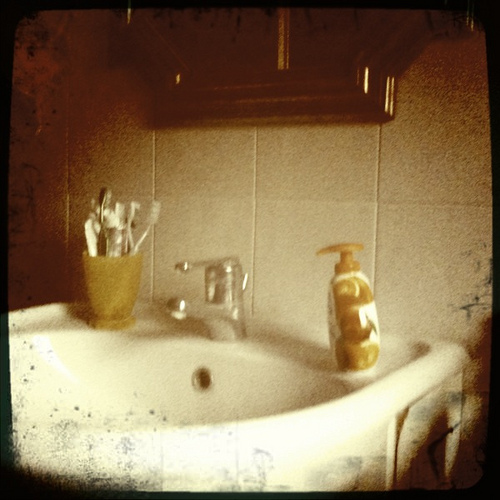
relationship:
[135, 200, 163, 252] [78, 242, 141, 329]
toothbrush in holder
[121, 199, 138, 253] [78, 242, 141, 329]
toothbrush in holder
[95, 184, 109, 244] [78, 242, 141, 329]
toothbrush in holder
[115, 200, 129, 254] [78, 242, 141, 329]
toothbrush in holder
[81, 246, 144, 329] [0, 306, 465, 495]
toothbrush holder on bathroom sink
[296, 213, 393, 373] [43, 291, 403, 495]
dispenser on wink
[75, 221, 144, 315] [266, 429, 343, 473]
toothbrush holder on sink edge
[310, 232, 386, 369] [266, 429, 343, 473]
soap dispenser on sink edge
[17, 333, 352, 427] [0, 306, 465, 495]
sinkbowl on bathroom sink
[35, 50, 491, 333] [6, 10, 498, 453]
tiles on wall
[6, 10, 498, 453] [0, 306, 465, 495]
wall behind bathroom sink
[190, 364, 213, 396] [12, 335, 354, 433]
hole has no water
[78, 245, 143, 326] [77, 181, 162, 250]
cup with toothbrushes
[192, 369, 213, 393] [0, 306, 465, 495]
hole of bathroom sink